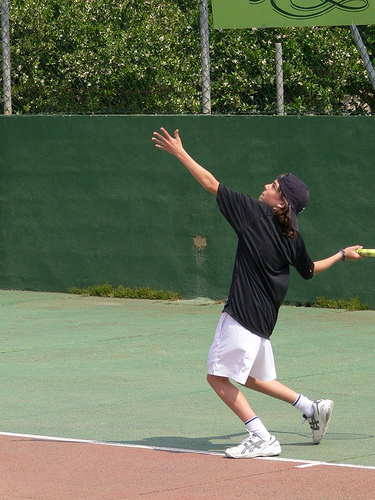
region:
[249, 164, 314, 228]
Boy wearing a black hat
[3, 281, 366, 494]
The court is green and red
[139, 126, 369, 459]
The boy is playing tennis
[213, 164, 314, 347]
Boy wearing a black shirt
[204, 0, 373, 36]
The sign is black and yellow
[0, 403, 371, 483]
White line on the court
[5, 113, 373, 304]
The wall is dark green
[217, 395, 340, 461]
The shoes are white with black stripes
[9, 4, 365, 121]
Green bushes behind the wall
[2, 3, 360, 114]
Grey chain link fence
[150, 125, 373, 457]
tennis player preparing to serve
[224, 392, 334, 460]
white tennis shoes with crew socks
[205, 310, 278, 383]
long white tennis shorts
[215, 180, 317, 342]
black polo shirt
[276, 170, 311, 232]
black baseball cap worn backwards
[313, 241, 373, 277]
lower right arm with watchband and racket handle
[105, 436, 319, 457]
shadow of tennis player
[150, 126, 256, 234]
tennis player's left arm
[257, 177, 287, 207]
tennis player's face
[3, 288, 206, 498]
red and green tennis court surface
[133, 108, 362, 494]
the kid is playing tennis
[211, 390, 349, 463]
Asic brand tennis shoes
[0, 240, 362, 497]
the court is red and green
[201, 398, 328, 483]
his foot is on the line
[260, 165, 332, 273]
he is wearing a backwards baseball cap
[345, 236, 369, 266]
his racket has a neon handle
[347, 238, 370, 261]
the grip is neon green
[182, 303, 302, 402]
a pair of white tennis shorts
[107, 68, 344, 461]
a boy readying to hit a tennis ball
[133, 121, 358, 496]
he is playing tennis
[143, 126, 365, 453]
Boy is wearing a black hat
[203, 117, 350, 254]
Black hat is worn backwards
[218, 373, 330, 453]
Blue top of the socks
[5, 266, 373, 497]
Tennis court is red and green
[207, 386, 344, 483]
Boy is wearing asic shoes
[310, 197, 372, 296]
Tennis racket in the left hand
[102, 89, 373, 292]
Boy is throwing ball up with left hand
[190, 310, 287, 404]
Tennis ball in the short pocket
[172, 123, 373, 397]
The boy has a black shirt on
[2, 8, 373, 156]
Trees are outside the tennis court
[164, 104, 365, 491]
boy prepares to serve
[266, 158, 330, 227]
boy has black hat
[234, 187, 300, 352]
boy has black shirt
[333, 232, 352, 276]
boy wears watch on right wrist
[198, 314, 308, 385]
boy wears white shorts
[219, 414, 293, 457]
white and black socks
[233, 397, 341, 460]
white and black shoes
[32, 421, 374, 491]
white base line on court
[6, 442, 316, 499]
clay red in-bounds area on court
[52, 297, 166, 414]
green out of play area on court